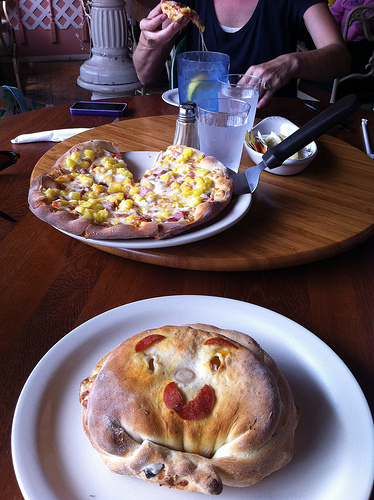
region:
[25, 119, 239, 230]
small pizza on plate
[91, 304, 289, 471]
small foldover on plate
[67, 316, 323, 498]
plate is white and round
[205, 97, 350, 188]
black handle on spatula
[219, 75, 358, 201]
spatula is under pizza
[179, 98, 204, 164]
pepper shaker behind pizza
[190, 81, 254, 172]
water glass behind pizza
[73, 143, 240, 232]
plate on round brown platter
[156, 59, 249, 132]
lemon in water glass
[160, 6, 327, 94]
person has black shirt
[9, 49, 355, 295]
pizza on a plate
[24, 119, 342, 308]
pizza on a white plate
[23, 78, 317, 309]
a personal size pizza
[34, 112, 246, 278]
a cooked pizza on plate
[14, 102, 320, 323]
a baked pizza on a plate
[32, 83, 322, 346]
a baked pizza on a white plate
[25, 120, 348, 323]
a pizza with pineapple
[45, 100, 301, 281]
pineapple on a pizza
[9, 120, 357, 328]
a small pizza on a plate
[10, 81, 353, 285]
small pizza on a table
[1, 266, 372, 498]
baked pastry on a white plate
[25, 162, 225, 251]
pizza with toppings on a white plate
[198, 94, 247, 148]
the top of a glass of cold water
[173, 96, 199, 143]
paper shaker with a silver top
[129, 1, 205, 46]
a woman's hand holding part of a slice of pizza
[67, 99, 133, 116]
blue cellphone on a wooden table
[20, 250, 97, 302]
top of a wooden table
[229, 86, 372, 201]
pizza slicer with a black handle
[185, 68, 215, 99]
slice of lemon in cold water in a blue tumbler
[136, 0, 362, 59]
part of a woman eating a slice of pizza wearing a black top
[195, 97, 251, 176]
a glass of water on a table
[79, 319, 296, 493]
a calzone on a white plate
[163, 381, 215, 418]
a bit of pepperoni shaped like a mouth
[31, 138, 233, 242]
a pizza with pineapple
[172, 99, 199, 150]
a salt shaker on a table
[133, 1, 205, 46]
a woman holding a slice of pizza in her hand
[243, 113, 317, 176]
a white bowl on a wooden table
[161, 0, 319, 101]
a woman wearing a black shirt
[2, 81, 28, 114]
a blue strap on top of a chair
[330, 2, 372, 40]
a person wearing a violet sweater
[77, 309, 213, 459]
This is a calzone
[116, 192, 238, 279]
This is a pizza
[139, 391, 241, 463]
This is broken pepperoni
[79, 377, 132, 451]
This is the crust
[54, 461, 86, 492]
This is a plate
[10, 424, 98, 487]
This is a white plate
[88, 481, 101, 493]
The plate is white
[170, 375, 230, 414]
The pepperoni is red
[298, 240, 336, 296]
This is a wooden plate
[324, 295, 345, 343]
The table is made of wood